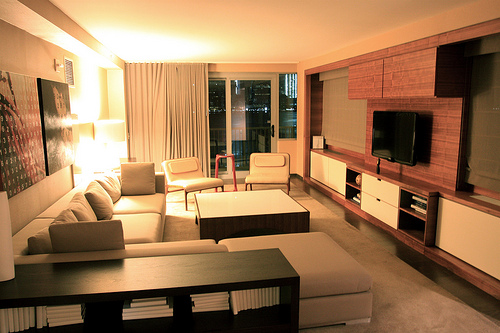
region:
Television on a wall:
[370, 108, 419, 166]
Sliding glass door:
[204, 69, 277, 176]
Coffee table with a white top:
[192, 185, 308, 240]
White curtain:
[125, 60, 210, 176]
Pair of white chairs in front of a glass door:
[160, 150, 290, 210]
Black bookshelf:
[0, 245, 297, 330]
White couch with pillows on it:
[7, 170, 372, 321]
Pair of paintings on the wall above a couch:
[0, 66, 75, 196]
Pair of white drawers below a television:
[358, 168, 398, 228]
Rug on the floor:
[160, 179, 499, 331]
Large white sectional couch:
[46, 159, 374, 325]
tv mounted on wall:
[371, 107, 427, 186]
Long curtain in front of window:
[125, 63, 216, 195]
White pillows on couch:
[53, 161, 156, 249]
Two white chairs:
[158, 146, 298, 206]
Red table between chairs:
[213, 151, 242, 192]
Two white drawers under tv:
[358, 173, 409, 232]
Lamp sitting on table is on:
[91, 111, 133, 178]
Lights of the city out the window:
[211, 82, 298, 117]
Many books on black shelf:
[8, 281, 302, 332]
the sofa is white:
[93, 195, 190, 246]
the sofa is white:
[132, 195, 229, 279]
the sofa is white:
[100, 181, 208, 263]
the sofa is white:
[107, 190, 253, 310]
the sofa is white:
[100, 156, 175, 236]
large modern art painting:
[37, 75, 74, 177]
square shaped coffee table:
[191, 187, 312, 241]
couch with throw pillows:
[16, 161, 228, 263]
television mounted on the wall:
[346, 46, 471, 196]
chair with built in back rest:
[243, 150, 291, 194]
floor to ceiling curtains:
[123, 61, 211, 183]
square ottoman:
[218, 228, 375, 325]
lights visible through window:
[211, 73, 299, 172]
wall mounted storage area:
[308, 143, 498, 303]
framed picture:
[311, 134, 327, 151]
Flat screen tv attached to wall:
[367, 105, 433, 167]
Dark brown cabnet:
[2, 242, 302, 328]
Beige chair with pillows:
[160, 155, 221, 207]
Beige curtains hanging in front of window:
[120, 58, 208, 191]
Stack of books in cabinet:
[116, 292, 176, 322]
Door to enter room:
[225, 73, 276, 178]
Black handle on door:
[266, 121, 276, 139]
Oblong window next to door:
[275, 68, 298, 143]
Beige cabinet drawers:
[357, 173, 398, 228]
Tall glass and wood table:
[212, 150, 240, 192]